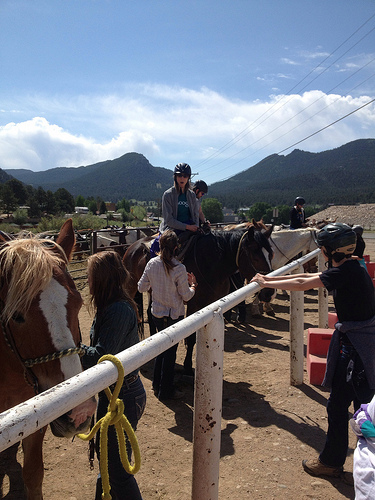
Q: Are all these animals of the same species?
A: Yes, all the animals are horses.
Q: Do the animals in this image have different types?
A: No, all the animals are horses.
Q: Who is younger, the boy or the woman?
A: The boy is younger than the woman.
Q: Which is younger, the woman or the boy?
A: The boy is younger than the woman.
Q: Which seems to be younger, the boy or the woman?
A: The boy is younger than the woman.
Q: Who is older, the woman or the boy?
A: The woman is older than the boy.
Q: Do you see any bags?
A: No, there are no bags.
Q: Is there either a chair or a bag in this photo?
A: No, there are no bags or chairs.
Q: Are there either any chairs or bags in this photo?
A: No, there are no bags or chairs.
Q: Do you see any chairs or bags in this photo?
A: No, there are no bags or chairs.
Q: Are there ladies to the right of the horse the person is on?
A: Yes, there is a lady to the right of the horse.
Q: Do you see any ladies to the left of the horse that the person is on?
A: No, the lady is to the right of the horse.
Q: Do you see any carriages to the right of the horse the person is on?
A: No, there is a lady to the right of the horse.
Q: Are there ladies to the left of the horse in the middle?
A: Yes, there is a lady to the left of the horse.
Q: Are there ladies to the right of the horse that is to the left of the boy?
A: No, the lady is to the left of the horse.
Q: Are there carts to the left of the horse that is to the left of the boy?
A: No, there is a lady to the left of the horse.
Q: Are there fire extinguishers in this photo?
A: No, there are no fire extinguishers.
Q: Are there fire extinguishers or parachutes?
A: No, there are no fire extinguishers or parachutes.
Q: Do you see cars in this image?
A: No, there are no cars.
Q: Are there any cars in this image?
A: No, there are no cars.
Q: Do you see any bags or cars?
A: No, there are no cars or bags.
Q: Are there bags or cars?
A: No, there are no cars or bags.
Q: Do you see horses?
A: Yes, there is a horse.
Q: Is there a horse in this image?
A: Yes, there is a horse.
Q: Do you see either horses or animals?
A: Yes, there is a horse.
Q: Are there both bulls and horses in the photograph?
A: No, there is a horse but no bulls.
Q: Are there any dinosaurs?
A: No, there are no dinosaurs.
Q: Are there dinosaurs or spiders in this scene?
A: No, there are no dinosaurs or spiders.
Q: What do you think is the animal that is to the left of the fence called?
A: The animal is a horse.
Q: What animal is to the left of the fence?
A: The animal is a horse.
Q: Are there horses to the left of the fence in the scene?
A: Yes, there is a horse to the left of the fence.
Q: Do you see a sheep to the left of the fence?
A: No, there is a horse to the left of the fence.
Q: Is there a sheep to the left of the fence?
A: No, there is a horse to the left of the fence.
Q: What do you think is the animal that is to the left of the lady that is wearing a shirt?
A: The animal is a horse.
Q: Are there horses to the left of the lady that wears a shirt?
A: Yes, there is a horse to the left of the lady.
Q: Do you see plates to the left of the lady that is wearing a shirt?
A: No, there is a horse to the left of the lady.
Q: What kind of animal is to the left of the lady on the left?
A: The animal is a horse.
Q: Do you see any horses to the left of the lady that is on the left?
A: Yes, there is a horse to the left of the lady.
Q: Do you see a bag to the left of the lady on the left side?
A: No, there is a horse to the left of the lady.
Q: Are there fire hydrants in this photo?
A: No, there are no fire hydrants.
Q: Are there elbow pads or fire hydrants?
A: No, there are no fire hydrants or elbow pads.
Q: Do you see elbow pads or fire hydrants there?
A: No, there are no fire hydrants or elbow pads.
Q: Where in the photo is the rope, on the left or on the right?
A: The rope is on the left of the image.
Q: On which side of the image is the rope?
A: The rope is on the left of the image.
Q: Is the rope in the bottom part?
A: Yes, the rope is in the bottom of the image.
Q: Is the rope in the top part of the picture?
A: No, the rope is in the bottom of the image.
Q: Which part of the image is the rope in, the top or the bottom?
A: The rope is in the bottom of the image.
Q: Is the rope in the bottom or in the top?
A: The rope is in the bottom of the image.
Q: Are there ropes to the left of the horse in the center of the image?
A: Yes, there is a rope to the left of the horse.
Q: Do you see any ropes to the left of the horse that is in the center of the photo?
A: Yes, there is a rope to the left of the horse.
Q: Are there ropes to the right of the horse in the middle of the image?
A: No, the rope is to the left of the horse.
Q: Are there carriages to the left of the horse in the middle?
A: No, there is a rope to the left of the horse.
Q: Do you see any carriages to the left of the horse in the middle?
A: No, there is a rope to the left of the horse.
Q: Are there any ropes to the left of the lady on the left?
A: Yes, there is a rope to the left of the lady.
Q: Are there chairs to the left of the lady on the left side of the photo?
A: No, there is a rope to the left of the lady.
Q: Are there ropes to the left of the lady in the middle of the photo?
A: Yes, there is a rope to the left of the lady.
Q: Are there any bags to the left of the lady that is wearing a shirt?
A: No, there is a rope to the left of the lady.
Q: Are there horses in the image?
A: Yes, there is a horse.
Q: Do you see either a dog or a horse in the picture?
A: Yes, there is a horse.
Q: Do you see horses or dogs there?
A: Yes, there is a horse.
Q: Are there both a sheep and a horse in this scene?
A: No, there is a horse but no sheep.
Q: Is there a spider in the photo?
A: No, there are no spiders.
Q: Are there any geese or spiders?
A: No, there are no spiders or geese.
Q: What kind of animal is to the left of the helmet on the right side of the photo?
A: The animal is a horse.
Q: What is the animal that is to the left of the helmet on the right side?
A: The animal is a horse.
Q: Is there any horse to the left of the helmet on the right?
A: Yes, there is a horse to the left of the helmet.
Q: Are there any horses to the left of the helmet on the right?
A: Yes, there is a horse to the left of the helmet.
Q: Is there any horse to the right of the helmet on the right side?
A: No, the horse is to the left of the helmet.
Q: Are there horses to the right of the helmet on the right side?
A: No, the horse is to the left of the helmet.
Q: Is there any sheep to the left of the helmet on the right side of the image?
A: No, there is a horse to the left of the helmet.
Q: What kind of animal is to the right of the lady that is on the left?
A: The animal is a horse.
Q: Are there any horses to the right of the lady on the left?
A: Yes, there is a horse to the right of the lady.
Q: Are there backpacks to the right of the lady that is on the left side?
A: No, there is a horse to the right of the lady.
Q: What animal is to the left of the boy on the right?
A: The animal is a horse.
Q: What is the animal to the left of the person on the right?
A: The animal is a horse.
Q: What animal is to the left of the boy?
A: The animal is a horse.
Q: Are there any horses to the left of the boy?
A: Yes, there is a horse to the left of the boy.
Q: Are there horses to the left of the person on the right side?
A: Yes, there is a horse to the left of the boy.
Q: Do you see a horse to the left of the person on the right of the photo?
A: Yes, there is a horse to the left of the boy.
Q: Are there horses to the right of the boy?
A: No, the horse is to the left of the boy.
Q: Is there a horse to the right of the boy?
A: No, the horse is to the left of the boy.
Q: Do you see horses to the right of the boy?
A: No, the horse is to the left of the boy.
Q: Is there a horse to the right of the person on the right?
A: No, the horse is to the left of the boy.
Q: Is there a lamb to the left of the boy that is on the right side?
A: No, there is a horse to the left of the boy.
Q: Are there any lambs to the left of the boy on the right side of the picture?
A: No, there is a horse to the left of the boy.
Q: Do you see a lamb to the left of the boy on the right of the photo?
A: No, there is a horse to the left of the boy.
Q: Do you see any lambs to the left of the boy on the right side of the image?
A: No, there is a horse to the left of the boy.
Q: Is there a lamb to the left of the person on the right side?
A: No, there is a horse to the left of the boy.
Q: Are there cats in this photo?
A: No, there are no cats.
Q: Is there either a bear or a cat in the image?
A: No, there are no cats or bears.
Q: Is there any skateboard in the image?
A: No, there are no skateboards.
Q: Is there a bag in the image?
A: No, there are no bags.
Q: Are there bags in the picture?
A: No, there are no bags.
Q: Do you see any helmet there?
A: Yes, there is a helmet.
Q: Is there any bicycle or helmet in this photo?
A: Yes, there is a helmet.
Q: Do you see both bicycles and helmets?
A: No, there is a helmet but no bicycles.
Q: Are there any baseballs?
A: No, there are no baseballs.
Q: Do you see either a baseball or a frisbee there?
A: No, there are no baseballs or frisbees.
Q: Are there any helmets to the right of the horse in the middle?
A: Yes, there is a helmet to the right of the horse.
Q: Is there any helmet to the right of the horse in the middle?
A: Yes, there is a helmet to the right of the horse.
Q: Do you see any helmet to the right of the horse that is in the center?
A: Yes, there is a helmet to the right of the horse.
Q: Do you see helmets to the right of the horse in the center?
A: Yes, there is a helmet to the right of the horse.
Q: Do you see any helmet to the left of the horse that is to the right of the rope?
A: No, the helmet is to the right of the horse.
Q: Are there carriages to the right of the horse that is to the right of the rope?
A: No, there is a helmet to the right of the horse.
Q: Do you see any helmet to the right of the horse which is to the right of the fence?
A: Yes, there is a helmet to the right of the horse.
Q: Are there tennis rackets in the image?
A: No, there are no tennis rackets.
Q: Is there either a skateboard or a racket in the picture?
A: No, there are no rackets or skateboards.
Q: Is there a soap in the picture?
A: No, there are no soaps.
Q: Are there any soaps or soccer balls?
A: No, there are no soaps or soccer balls.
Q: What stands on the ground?
A: The pole stands on the ground.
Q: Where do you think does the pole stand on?
A: The pole stands on the ground.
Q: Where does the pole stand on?
A: The pole stands on the ground.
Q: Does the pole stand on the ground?
A: Yes, the pole stands on the ground.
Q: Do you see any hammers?
A: No, there are no hammers.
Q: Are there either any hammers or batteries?
A: No, there are no hammers or batteries.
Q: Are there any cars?
A: No, there are no cars.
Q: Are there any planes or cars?
A: No, there are no cars or planes.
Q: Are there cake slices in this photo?
A: No, there are no cake slices.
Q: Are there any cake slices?
A: No, there are no cake slices.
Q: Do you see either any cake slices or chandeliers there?
A: No, there are no cake slices or chandeliers.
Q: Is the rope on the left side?
A: Yes, the rope is on the left of the image.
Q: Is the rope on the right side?
A: No, the rope is on the left of the image.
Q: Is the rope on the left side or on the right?
A: The rope is on the left of the image.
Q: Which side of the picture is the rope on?
A: The rope is on the left of the image.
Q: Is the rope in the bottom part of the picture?
A: Yes, the rope is in the bottom of the image.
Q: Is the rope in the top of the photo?
A: No, the rope is in the bottom of the image.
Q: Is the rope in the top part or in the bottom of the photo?
A: The rope is in the bottom of the image.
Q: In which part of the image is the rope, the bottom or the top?
A: The rope is in the bottom of the image.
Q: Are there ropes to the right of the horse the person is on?
A: Yes, there is a rope to the right of the horse.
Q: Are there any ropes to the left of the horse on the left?
A: No, the rope is to the right of the horse.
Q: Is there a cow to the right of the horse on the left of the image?
A: No, there is a rope to the right of the horse.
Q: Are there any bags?
A: No, there are no bags.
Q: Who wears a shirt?
A: The lady wears a shirt.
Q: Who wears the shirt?
A: The lady wears a shirt.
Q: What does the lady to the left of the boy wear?
A: The lady wears a shirt.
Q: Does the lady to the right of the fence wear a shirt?
A: Yes, the lady wears a shirt.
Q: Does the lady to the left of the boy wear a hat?
A: No, the lady wears a shirt.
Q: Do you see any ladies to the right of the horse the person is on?
A: Yes, there is a lady to the right of the horse.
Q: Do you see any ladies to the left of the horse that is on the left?
A: No, the lady is to the right of the horse.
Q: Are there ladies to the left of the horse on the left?
A: No, the lady is to the right of the horse.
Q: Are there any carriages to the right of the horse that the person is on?
A: No, there is a lady to the right of the horse.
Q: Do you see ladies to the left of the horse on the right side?
A: Yes, there is a lady to the left of the horse.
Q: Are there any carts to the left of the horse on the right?
A: No, there is a lady to the left of the horse.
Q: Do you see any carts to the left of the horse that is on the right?
A: No, there is a lady to the left of the horse.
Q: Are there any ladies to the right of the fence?
A: Yes, there is a lady to the right of the fence.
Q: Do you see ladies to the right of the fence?
A: Yes, there is a lady to the right of the fence.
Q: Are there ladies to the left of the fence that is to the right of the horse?
A: No, the lady is to the right of the fence.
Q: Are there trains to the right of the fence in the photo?
A: No, there is a lady to the right of the fence.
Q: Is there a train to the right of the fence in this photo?
A: No, there is a lady to the right of the fence.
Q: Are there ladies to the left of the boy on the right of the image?
A: Yes, there is a lady to the left of the boy.